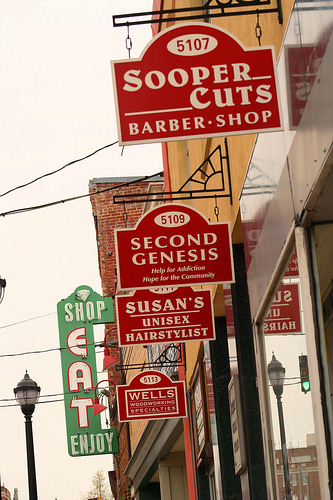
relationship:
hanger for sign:
[108, 135, 233, 208] [110, 201, 234, 291]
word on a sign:
[132, 248, 218, 268] [110, 201, 234, 291]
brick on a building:
[99, 212, 114, 218] [88, 174, 197, 497]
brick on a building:
[97, 218, 109, 224] [88, 174, 197, 497]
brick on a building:
[105, 193, 115, 197] [88, 174, 197, 497]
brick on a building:
[101, 269, 115, 274] [88, 174, 197, 497]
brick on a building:
[99, 239, 108, 244] [88, 174, 197, 497]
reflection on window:
[258, 313, 310, 499] [255, 240, 323, 499]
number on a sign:
[149, 25, 227, 59] [111, 172, 263, 288]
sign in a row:
[50, 19, 306, 494] [95, 10, 289, 472]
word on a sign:
[47, 321, 108, 431] [55, 281, 121, 459]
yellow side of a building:
[95, 1, 294, 459] [75, 0, 332, 499]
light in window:
[302, 381, 309, 389] [255, 240, 323, 499]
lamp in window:
[239, 324, 316, 496] [255, 240, 323, 499]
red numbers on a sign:
[154, 211, 198, 227] [110, 201, 234, 291]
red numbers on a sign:
[137, 372, 166, 384] [114, 367, 192, 421]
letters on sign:
[125, 229, 227, 271] [90, 191, 238, 289]